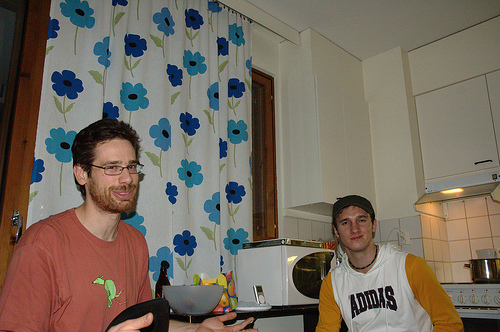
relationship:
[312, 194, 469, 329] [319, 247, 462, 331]
man wearing shirt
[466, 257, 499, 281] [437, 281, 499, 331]
pot on top of stove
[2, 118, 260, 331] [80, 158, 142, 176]
man wearing glasses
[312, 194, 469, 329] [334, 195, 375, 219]
man wearing hat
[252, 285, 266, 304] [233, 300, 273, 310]
ipod resting on docking station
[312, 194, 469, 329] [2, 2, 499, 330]
man located in kitchen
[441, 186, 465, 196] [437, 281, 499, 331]
light over stove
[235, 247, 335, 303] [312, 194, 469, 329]
microwave behind man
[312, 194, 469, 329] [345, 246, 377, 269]
man wearing necklace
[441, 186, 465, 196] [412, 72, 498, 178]
light under cabinet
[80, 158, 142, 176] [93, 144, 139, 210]
glasses located on face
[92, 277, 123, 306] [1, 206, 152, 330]
dog printed on shirt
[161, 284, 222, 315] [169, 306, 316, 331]
bowl on top of counter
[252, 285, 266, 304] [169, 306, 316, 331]
music player on top of counter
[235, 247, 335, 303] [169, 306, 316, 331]
microwave on top of counter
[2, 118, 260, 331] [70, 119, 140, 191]
man has hair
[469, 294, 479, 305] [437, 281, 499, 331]
knob on front of stove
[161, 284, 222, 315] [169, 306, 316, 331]
bowl sitting on top of counter